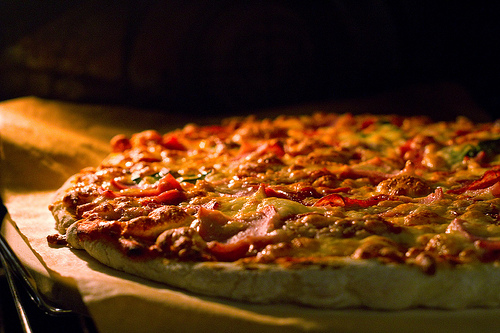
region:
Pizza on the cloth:
[42, 105, 497, 306]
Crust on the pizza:
[81, 235, 498, 313]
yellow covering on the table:
[0, 97, 497, 332]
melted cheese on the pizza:
[247, 195, 302, 222]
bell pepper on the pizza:
[445, 141, 478, 170]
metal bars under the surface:
[0, 238, 72, 330]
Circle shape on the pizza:
[42, 108, 496, 315]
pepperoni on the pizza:
[318, 189, 381, 212]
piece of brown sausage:
[472, 148, 491, 169]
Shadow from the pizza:
[70, 247, 285, 330]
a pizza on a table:
[103, 86, 310, 318]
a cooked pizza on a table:
[104, 68, 421, 332]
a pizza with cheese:
[62, 65, 406, 325]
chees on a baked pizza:
[54, 51, 376, 317]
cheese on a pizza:
[87, 79, 400, 329]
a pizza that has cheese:
[57, 109, 365, 331]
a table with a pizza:
[26, 65, 385, 327]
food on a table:
[104, 90, 471, 331]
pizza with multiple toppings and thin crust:
[46, 109, 498, 304]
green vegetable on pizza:
[123, 167, 213, 192]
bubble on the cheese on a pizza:
[372, 171, 434, 201]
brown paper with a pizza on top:
[1, 97, 498, 332]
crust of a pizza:
[52, 173, 499, 311]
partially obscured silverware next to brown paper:
[1, 206, 80, 332]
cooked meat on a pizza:
[103, 174, 181, 201]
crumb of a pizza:
[43, 231, 67, 245]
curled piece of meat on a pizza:
[305, 189, 398, 214]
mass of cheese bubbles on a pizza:
[113, 202, 203, 260]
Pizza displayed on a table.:
[41, 41, 491, 308]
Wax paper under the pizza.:
[6, 88, 102, 245]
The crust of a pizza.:
[47, 185, 155, 284]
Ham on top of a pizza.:
[198, 214, 279, 259]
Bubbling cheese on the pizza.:
[235, 183, 316, 230]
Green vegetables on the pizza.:
[445, 134, 480, 168]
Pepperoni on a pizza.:
[302, 178, 380, 221]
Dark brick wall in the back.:
[35, 21, 234, 97]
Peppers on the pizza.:
[438, 128, 478, 162]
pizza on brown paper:
[49, 108, 499, 329]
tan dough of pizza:
[160, 256, 499, 316]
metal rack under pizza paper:
[2, 242, 77, 332]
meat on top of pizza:
[261, 170, 398, 213]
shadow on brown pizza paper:
[1, 125, 78, 212]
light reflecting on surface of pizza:
[193, 137, 209, 152]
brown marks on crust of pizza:
[298, 258, 349, 275]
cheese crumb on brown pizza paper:
[44, 231, 71, 251]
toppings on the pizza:
[141, 128, 406, 266]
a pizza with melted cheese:
[209, 116, 356, 234]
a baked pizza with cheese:
[225, 95, 498, 312]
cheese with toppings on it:
[269, 151, 391, 218]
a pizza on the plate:
[93, 89, 370, 330]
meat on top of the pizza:
[346, 171, 391, 212]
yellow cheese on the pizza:
[262, 153, 414, 269]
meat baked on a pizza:
[145, 106, 477, 281]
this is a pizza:
[32, 104, 494, 318]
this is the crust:
[37, 189, 499, 329]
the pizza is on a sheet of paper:
[25, 83, 483, 331]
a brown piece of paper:
[4, 176, 323, 331]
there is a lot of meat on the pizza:
[19, 86, 499, 308]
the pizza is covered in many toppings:
[28, 103, 498, 310]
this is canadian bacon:
[184, 200, 286, 252]